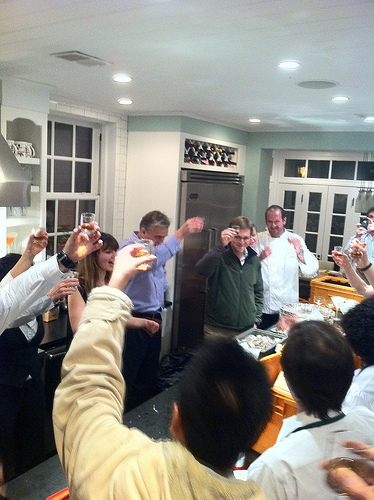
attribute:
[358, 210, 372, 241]
man — white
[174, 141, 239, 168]
wine rack — white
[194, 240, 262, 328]
jacket — green jacket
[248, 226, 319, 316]
shirt — white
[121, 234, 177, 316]
shirt — blue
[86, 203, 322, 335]
people — toast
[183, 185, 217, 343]
refrigerator door — stainless steel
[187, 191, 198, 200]
logo — black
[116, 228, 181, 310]
shirt — blue, dressy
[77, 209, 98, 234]
glasses — white, frosted, martini glasses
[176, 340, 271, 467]
head — back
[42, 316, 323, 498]
table — dark gray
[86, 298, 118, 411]
jacket — beige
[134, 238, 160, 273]
glass — shot glass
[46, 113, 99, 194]
window — dark, white frame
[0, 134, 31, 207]
oven hood — stainless steel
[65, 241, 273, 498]
person — turned away